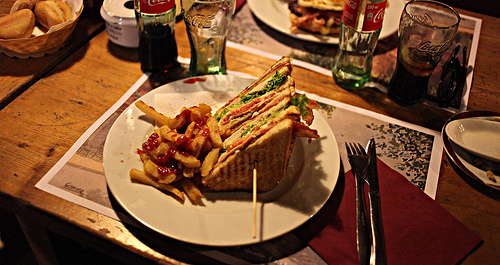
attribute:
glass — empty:
[179, 0, 237, 76]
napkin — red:
[376, 172, 438, 260]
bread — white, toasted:
[202, 119, 294, 192]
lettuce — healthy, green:
[238, 71, 294, 106]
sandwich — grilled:
[226, 79, 297, 184]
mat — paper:
[31, 50, 444, 262]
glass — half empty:
[398, 9, 450, 74]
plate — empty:
[443, 110, 499, 169]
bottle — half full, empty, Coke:
[135, 1, 180, 74]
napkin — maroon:
[318, 157, 485, 263]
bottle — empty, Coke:
[332, 2, 386, 90]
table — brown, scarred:
[2, 1, 499, 263]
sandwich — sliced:
[203, 52, 298, 195]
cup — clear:
[386, 0, 458, 110]